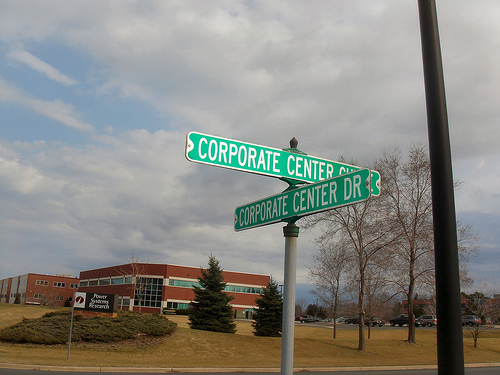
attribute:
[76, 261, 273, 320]
building — brick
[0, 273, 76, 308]
building — brick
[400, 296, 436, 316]
building — brick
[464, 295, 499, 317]
building — brick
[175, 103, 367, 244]
pole — tall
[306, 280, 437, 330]
mountain range — small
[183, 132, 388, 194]
sign — green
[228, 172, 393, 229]
sign — green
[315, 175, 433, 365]
trees — bare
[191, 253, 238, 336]
pine tree — needle-filled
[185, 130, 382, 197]
sign — green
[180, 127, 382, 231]
text — white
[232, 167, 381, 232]
street sign — green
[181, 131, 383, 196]
street sign — green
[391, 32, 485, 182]
pole — long, wooden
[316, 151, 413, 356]
trees — barren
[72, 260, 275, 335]
building — office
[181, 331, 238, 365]
grass — brown, green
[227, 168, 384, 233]
sign — green 